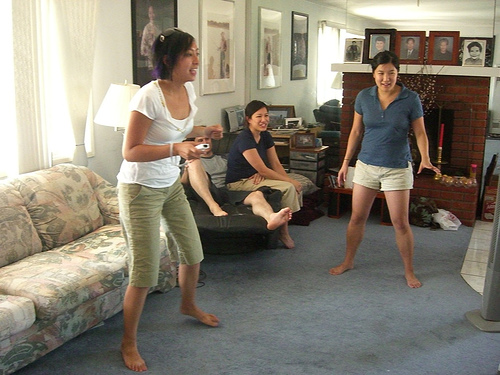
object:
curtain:
[20, 0, 90, 140]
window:
[2, 0, 97, 171]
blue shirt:
[351, 82, 424, 169]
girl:
[325, 51, 442, 289]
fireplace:
[337, 70, 490, 225]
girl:
[116, 29, 223, 373]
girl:
[223, 99, 308, 230]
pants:
[117, 177, 204, 288]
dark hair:
[150, 27, 196, 81]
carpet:
[28, 228, 500, 375]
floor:
[96, 218, 499, 372]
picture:
[341, 35, 366, 64]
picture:
[362, 27, 393, 64]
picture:
[396, 28, 426, 62]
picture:
[428, 30, 461, 64]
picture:
[462, 37, 486, 67]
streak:
[149, 63, 160, 77]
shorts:
[352, 160, 415, 191]